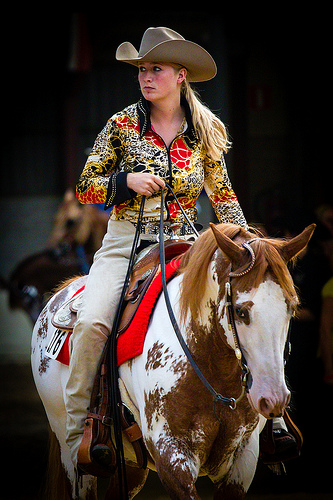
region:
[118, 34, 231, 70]
woman has tan hat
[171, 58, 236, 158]
woman has blonde hair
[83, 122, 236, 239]
yellow and black shirt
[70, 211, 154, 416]
woman has white pants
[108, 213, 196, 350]
woman on brown saddle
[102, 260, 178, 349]
woman on red cloth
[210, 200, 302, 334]
horse has brown mane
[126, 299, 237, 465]
brown and white horse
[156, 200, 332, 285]
horse has brown ears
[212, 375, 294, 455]
horse has pink nose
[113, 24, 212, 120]
face of the girl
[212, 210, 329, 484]
face of the horse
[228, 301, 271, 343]
eye of the horse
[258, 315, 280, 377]
white skin of horse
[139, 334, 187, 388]
brown marks on the skin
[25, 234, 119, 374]
leg of the girl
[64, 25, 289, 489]
a girl sitting in the horse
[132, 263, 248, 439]
a thread tied to horse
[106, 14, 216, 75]
a girl wearing hat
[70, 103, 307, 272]
a girl wearing shirt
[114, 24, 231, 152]
blond woman wearing a cowboy hat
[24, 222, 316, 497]
brown and white horse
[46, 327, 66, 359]
number on the side of the horse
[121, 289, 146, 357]
red blanket under the horse saddle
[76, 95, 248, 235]
woman's brightly colored shirt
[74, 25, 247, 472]
woman riding a horse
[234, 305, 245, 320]
horse's eye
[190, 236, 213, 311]
horse's mane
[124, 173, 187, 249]
woman's hand holding the reins of a horse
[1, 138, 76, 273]
out of focus background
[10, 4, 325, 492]
woman sitting on a horse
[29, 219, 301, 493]
a white and brown horse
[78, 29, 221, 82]
woman wearing a beige cowboy hat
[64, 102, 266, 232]
woman wearing yellow, red, and black jacket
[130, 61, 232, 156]
woman has blonde hair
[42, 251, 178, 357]
red blanket under a saddle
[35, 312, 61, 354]
contestant numbe 176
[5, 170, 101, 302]
horses behind the woman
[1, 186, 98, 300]
horses behind the woman are blurry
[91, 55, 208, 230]
woman is looking left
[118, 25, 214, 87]
a woman wearing a hat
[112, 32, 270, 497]
a woman riding a horse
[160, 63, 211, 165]
a woman with blonde hair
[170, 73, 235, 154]
a woman with long hair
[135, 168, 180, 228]
a woman holding a set of reins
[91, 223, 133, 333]
a woman wearing tan pants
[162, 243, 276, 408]
a brown and white horse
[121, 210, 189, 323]
a leather saddle on a horse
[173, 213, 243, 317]
a brown mane on a horse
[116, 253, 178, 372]
a red blanket on a horse